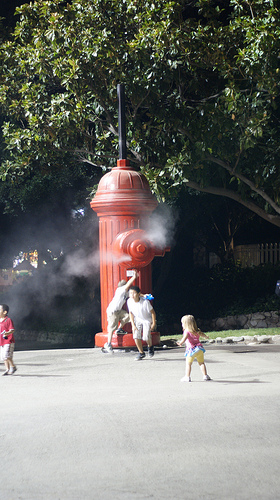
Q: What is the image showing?
A: It is showing a road.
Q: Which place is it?
A: It is a road.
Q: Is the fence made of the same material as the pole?
A: No, the fence is made of wood and the pole is made of metal.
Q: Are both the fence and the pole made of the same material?
A: No, the fence is made of wood and the pole is made of metal.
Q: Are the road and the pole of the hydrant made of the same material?
A: No, the road is made of concrete and the pole is made of metal.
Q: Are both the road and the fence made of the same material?
A: No, the road is made of cement and the fence is made of wood.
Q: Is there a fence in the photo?
A: Yes, there is a fence.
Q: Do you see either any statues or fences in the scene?
A: Yes, there is a fence.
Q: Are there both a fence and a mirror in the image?
A: No, there is a fence but no mirrors.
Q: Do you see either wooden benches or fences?
A: Yes, there is a wood fence.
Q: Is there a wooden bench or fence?
A: Yes, there is a wood fence.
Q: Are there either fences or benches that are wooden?
A: Yes, the fence is wooden.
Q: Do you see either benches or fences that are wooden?
A: Yes, the fence is wooden.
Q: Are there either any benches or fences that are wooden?
A: Yes, the fence is wooden.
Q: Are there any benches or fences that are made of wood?
A: Yes, the fence is made of wood.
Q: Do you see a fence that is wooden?
A: Yes, there is a wood fence.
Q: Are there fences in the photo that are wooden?
A: Yes, there is a fence that is wooden.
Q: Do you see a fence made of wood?
A: Yes, there is a fence that is made of wood.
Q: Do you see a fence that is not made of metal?
A: Yes, there is a fence that is made of wood.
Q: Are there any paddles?
A: No, there are no paddles.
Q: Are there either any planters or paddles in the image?
A: No, there are no paddles or planters.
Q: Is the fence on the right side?
A: Yes, the fence is on the right of the image.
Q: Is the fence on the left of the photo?
A: No, the fence is on the right of the image.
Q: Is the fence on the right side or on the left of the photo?
A: The fence is on the right of the image.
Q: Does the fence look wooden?
A: Yes, the fence is wooden.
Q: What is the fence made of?
A: The fence is made of wood.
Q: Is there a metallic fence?
A: No, there is a fence but it is wooden.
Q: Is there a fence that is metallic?
A: No, there is a fence but it is wooden.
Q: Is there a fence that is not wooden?
A: No, there is a fence but it is wooden.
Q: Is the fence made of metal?
A: No, the fence is made of wood.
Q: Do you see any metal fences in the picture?
A: No, there is a fence but it is made of wood.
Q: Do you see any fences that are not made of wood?
A: No, there is a fence but it is made of wood.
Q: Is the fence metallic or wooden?
A: The fence is wooden.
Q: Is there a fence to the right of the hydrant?
A: Yes, there is a fence to the right of the hydrant.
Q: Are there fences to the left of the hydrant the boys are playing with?
A: No, the fence is to the right of the fire hydrant.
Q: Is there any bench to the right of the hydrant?
A: No, there is a fence to the right of the hydrant.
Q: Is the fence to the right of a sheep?
A: No, the fence is to the right of the fire hydrant.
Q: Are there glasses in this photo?
A: No, there are no glasses.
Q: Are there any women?
A: No, there are no women.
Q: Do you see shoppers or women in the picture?
A: No, there are no women or shoppers.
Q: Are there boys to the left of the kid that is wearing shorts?
A: Yes, there are boys to the left of the kid.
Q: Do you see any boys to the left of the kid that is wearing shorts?
A: Yes, there are boys to the left of the kid.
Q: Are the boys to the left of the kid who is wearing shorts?
A: Yes, the boys are to the left of the kid.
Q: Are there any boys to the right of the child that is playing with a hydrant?
A: Yes, there are boys to the right of the child.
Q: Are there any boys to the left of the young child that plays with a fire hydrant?
A: No, the boys are to the right of the child.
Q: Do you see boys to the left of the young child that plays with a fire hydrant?
A: No, the boys are to the right of the child.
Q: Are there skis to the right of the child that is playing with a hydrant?
A: No, there are boys to the right of the child.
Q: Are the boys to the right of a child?
A: Yes, the boys are to the right of a child.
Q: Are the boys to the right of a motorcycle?
A: No, the boys are to the right of a child.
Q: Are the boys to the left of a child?
A: No, the boys are to the right of a child.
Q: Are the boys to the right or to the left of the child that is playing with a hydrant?
A: The boys are to the right of the child.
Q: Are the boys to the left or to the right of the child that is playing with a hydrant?
A: The boys are to the right of the child.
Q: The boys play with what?
A: The boys play with a hydrant.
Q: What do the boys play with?
A: The boys play with a hydrant.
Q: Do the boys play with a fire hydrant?
A: Yes, the boys play with a fire hydrant.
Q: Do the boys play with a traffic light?
A: No, the boys play with a fire hydrant.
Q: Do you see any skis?
A: No, there are no skis.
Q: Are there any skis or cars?
A: No, there are no skis or cars.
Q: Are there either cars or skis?
A: No, there are no skis or cars.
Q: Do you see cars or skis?
A: No, there are no skis or cars.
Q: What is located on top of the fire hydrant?
A: The pole is on top of the fire hydrant.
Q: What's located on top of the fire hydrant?
A: The pole is on top of the fire hydrant.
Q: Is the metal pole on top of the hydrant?
A: Yes, the pole is on top of the hydrant.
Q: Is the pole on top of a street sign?
A: No, the pole is on top of the hydrant.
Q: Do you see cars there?
A: No, there are no cars.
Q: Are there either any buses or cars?
A: No, there are no cars or buses.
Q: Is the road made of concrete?
A: Yes, the road is made of concrete.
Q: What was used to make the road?
A: The road is made of cement.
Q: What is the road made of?
A: The road is made of concrete.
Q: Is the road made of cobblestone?
A: No, the road is made of concrete.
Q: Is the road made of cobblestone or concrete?
A: The road is made of concrete.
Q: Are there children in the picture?
A: Yes, there is a child.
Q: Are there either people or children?
A: Yes, there is a child.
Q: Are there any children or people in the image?
A: Yes, there is a child.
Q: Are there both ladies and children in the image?
A: No, there is a child but no ladies.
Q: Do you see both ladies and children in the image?
A: No, there is a child but no ladies.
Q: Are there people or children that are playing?
A: Yes, the child is playing.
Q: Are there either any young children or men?
A: Yes, there is a young child.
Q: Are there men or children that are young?
A: Yes, the child is young.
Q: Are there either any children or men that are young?
A: Yes, the child is young.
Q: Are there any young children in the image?
A: Yes, there is a young child.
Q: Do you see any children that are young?
A: Yes, there is a child that is young.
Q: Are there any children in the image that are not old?
A: Yes, there is an young child.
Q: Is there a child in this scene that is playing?
A: Yes, there is a child that is playing.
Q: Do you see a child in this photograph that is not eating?
A: Yes, there is a child that is playing .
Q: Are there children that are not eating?
A: Yes, there is a child that is playing.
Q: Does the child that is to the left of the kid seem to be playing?
A: Yes, the child is playing.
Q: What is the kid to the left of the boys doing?
A: The child is playing.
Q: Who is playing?
A: The kid is playing.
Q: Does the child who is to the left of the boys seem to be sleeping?
A: No, the kid is playing.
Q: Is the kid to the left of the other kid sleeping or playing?
A: The kid is playing.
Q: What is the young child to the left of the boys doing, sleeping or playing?
A: The kid is playing.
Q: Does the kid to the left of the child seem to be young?
A: Yes, the child is young.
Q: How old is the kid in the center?
A: The kid is young.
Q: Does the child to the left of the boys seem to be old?
A: No, the child is young.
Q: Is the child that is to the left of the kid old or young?
A: The kid is young.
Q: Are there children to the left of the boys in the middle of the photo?
A: Yes, there is a child to the left of the boys.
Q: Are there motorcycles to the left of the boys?
A: No, there is a child to the left of the boys.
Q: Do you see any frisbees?
A: No, there are no frisbees.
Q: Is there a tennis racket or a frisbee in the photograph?
A: No, there are no frisbees or rackets.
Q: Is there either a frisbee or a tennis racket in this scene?
A: No, there are no frisbees or rackets.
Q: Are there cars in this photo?
A: No, there are no cars.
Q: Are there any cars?
A: No, there are no cars.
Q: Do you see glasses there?
A: No, there are no glasses.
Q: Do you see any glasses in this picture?
A: No, there are no glasses.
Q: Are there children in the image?
A: Yes, there is a child.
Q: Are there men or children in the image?
A: Yes, there is a child.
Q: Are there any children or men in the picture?
A: Yes, there is a child.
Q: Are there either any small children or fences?
A: Yes, there is a small child.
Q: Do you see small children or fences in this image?
A: Yes, there is a small child.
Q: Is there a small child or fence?
A: Yes, there is a small child.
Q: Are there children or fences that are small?
A: Yes, the child is small.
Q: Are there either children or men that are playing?
A: Yes, the child is playing.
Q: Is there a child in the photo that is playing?
A: Yes, there is a child that is playing.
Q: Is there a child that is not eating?
A: Yes, there is a child that is playing.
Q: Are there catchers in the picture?
A: No, there are no catchers.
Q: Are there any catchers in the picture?
A: No, there are no catchers.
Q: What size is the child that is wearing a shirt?
A: The kid is small.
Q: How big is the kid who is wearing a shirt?
A: The child is small.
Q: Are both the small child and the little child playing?
A: Yes, both the child and the kid are playing.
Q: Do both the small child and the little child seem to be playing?
A: Yes, both the child and the kid are playing.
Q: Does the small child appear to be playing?
A: Yes, the child is playing.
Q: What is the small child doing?
A: The child is playing.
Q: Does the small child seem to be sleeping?
A: No, the kid is playing.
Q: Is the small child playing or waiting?
A: The child is playing.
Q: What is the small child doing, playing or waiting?
A: The child is playing.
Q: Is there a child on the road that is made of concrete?
A: Yes, there is a child on the road.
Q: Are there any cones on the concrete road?
A: No, there is a child on the road.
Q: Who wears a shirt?
A: The child wears a shirt.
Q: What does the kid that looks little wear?
A: The kid wears a shirt.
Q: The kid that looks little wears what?
A: The kid wears a shirt.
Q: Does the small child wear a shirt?
A: Yes, the kid wears a shirt.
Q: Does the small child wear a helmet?
A: No, the kid wears a shirt.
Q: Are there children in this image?
A: Yes, there is a child.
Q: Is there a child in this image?
A: Yes, there is a child.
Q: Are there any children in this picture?
A: Yes, there is a child.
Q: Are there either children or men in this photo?
A: Yes, there is a child.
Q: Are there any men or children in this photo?
A: Yes, there is a child.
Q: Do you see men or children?
A: Yes, there is a child.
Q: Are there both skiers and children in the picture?
A: No, there is a child but no skiers.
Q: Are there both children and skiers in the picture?
A: No, there is a child but no skiers.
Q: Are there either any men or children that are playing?
A: Yes, the child is playing.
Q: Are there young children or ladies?
A: Yes, there is a young child.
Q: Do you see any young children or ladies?
A: Yes, there is a young child.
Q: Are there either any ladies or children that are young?
A: Yes, the child is young.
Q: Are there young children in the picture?
A: Yes, there is a young child.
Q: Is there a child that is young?
A: Yes, there is a child that is young.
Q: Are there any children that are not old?
A: Yes, there is an young child.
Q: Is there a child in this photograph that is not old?
A: Yes, there is an young child.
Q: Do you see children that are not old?
A: Yes, there is an young child.